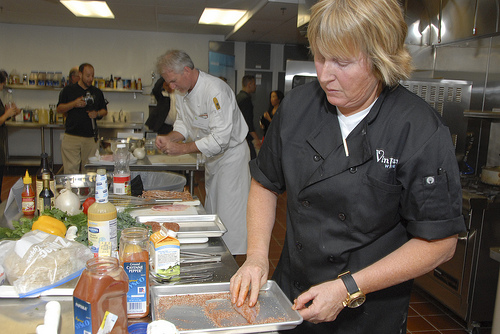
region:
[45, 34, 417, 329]
People in the kitchen.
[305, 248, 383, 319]
Man wearing a watch.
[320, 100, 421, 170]
Logo on the man's shirt.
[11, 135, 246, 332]
Food on the table.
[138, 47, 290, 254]
Man in a white uniform.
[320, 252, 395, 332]
Black and gold watch.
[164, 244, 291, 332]
Tray on the table.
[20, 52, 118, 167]
Shelves in the background.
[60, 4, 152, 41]
Light on the ceiling.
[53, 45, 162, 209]
Man in a black shirt.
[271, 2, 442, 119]
Person is looking down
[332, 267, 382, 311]
He is wearing a watch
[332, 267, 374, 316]
Watch is black and gold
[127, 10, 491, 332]
People are preparing food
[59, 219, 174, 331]
Opened containers on the table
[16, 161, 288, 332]
Table is silver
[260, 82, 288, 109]
Woman is talking in the background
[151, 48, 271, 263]
He is wearing a white coat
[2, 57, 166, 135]
Items on the rack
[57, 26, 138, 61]
The paint is white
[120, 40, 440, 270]
These people are chefs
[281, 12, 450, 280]
This chef is a woman wearing a black coat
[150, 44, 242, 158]
This chef is a man wearing a white coat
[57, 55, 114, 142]
This man is holding a camera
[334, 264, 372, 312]
The watch is gold with a black strap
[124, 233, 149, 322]
A large plastic jar holding cayenne pepper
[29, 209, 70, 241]
A yellow pepper that has not been cut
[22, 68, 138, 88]
A shelf holding many items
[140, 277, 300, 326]
A silver colored pan in a kitchen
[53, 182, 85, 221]
A large white onion that has not been peeled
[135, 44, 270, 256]
a man cooking wearing a white apron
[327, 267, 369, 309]
a wristwatch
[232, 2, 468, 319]
someone cooking wearing a dark apron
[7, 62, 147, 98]
food and other items on a shelf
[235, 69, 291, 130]
a man and a woman talking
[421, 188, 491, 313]
an oven in a kitchen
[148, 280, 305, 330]
a tray being prepared for cooking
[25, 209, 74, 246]
an orange pepper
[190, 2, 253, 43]
lights on the ceiling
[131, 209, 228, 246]
some meat on a tray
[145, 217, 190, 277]
A small orange/white/blue carton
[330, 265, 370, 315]
A gold/black wrist watch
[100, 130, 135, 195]
A bottle of oil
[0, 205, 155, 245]
A pile of greens on a table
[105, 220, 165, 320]
A jar of crushed pepper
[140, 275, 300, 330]
A tray full of spices/breading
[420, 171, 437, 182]
A white logo on a shirt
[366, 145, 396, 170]
white writing on a black shirt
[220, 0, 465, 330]
A woman rolling chicken in a tray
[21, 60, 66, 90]
A collection of jarred goods in the back